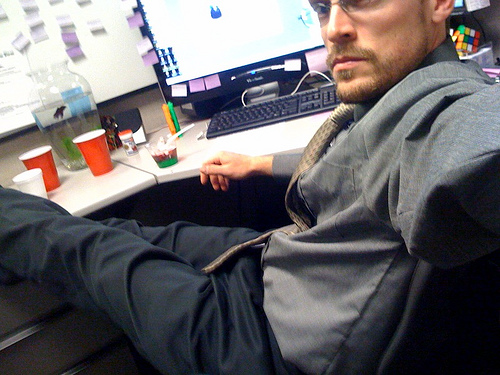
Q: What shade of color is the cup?
A: Red.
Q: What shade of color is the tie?
A: Brown.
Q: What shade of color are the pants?
A: Black.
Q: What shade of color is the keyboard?
A: Black.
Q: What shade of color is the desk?
A: White.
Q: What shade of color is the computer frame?
A: Black.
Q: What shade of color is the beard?
A: Brown.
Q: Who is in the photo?
A: A man.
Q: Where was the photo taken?
A: In a room.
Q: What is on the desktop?
A: A computer monitor.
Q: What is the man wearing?
A: Suit and tie.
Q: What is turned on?
A: The computer.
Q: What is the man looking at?
A: Camera.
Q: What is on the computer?
A: Notes.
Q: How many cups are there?
A: Two.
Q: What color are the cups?
A: Red.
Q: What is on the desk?
A: A computer.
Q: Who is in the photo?
A: A man.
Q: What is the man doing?
A: Sitting in a chair.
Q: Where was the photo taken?
A: In an office.